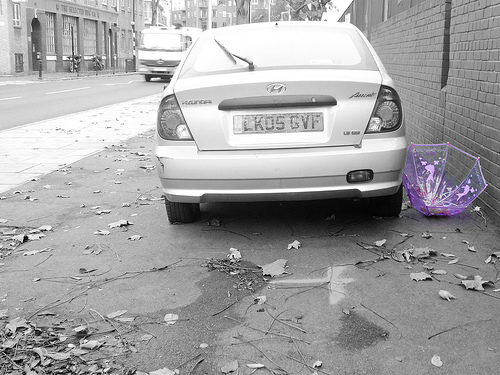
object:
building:
[351, 0, 499, 237]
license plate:
[233, 112, 324, 135]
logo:
[181, 99, 212, 105]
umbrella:
[401, 142, 488, 217]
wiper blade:
[214, 39, 255, 71]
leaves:
[257, 259, 290, 278]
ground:
[0, 92, 499, 374]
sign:
[348, 91, 377, 99]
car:
[154, 21, 408, 224]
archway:
[30, 16, 43, 71]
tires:
[164, 196, 199, 223]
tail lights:
[156, 94, 194, 141]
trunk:
[172, 68, 382, 151]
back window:
[178, 21, 380, 79]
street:
[1, 260, 69, 374]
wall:
[459, 0, 499, 123]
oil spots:
[129, 259, 272, 375]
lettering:
[343, 130, 360, 135]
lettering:
[56, 3, 100, 19]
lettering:
[350, 91, 377, 98]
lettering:
[182, 99, 213, 104]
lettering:
[243, 115, 320, 132]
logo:
[266, 82, 287, 95]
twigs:
[1, 259, 183, 375]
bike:
[66, 56, 81, 73]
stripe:
[0, 79, 145, 102]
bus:
[135, 22, 203, 82]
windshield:
[137, 33, 185, 52]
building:
[0, 0, 166, 75]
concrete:
[1, 235, 497, 374]